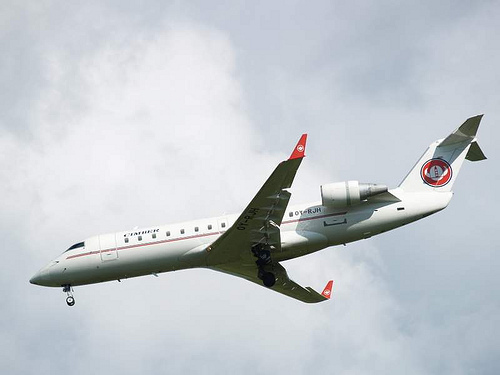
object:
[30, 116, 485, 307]
plane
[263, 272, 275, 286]
wheels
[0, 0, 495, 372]
sky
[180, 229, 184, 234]
windows